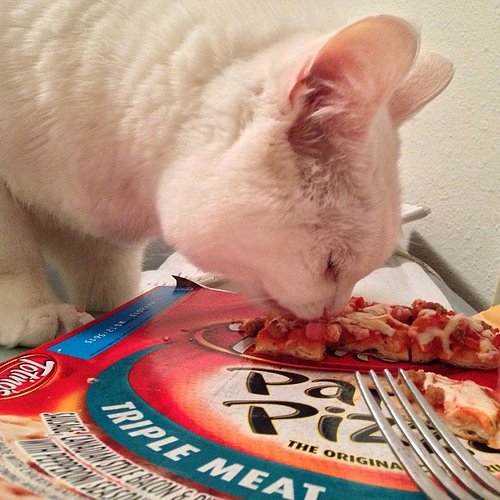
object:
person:
[286, 119, 428, 203]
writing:
[348, 413, 500, 455]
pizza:
[239, 295, 500, 371]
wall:
[378, 1, 495, 311]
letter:
[317, 406, 344, 442]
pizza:
[397, 368, 500, 449]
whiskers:
[207, 292, 294, 321]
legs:
[0, 213, 58, 299]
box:
[0, 275, 499, 498]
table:
[1, 0, 496, 499]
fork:
[354, 367, 500, 499]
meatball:
[412, 299, 447, 316]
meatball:
[266, 316, 290, 337]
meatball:
[239, 314, 264, 334]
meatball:
[425, 384, 445, 406]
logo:
[0, 358, 55, 397]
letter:
[222, 399, 318, 435]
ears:
[289, 14, 421, 120]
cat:
[0, 0, 457, 349]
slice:
[238, 296, 500, 370]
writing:
[226, 367, 358, 408]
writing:
[242, 377, 324, 496]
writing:
[101, 400, 201, 463]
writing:
[196, 456, 326, 500]